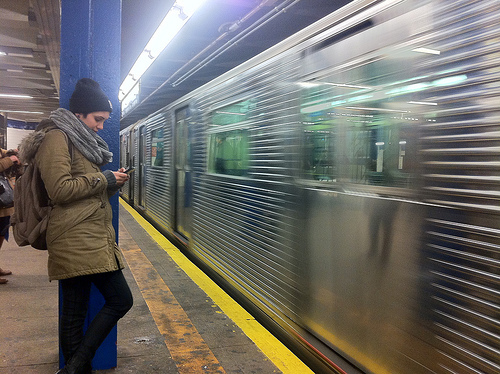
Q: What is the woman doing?
A: Texting.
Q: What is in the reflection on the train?
A: The person standing in front.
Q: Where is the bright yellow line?
A: Edge of the platform.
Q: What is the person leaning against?
A: Blue beam.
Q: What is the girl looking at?
A: Her phone.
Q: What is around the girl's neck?
A: Grey scarf.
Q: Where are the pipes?
A: In the ceiling above the train.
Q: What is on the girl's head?
A: Black hat.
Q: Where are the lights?
A: Above the train.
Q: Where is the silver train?
A: On the tracks.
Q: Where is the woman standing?
A: In the subway station.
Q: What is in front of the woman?
A: A subway.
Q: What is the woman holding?
A: A cell phone.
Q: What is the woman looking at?
A: A cell phone.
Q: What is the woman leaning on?
A: A pole.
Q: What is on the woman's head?
A: A hat.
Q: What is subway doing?
A: Moving.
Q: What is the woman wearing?
A: A coat.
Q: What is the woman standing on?
A: A platform.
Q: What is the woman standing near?
A: The subway doors.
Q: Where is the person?
A: At a train station.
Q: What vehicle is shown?
A: Train.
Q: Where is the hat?
A: On the person's head.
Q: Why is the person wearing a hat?
A: To stay warm.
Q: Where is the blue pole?
A: Behind the woman.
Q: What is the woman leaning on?
A: Blue pole.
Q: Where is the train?
A: Beside the woman.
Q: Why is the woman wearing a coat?
A: Warmth.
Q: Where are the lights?
A: On the ceiling.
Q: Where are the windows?
A: On the train.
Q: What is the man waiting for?
A: Train.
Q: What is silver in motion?
A: Train.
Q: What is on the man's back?
A: Backpack.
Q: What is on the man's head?
A: A beanie.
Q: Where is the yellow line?
A: On pavement.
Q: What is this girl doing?
A: Texting.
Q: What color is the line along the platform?
A: Yellow.